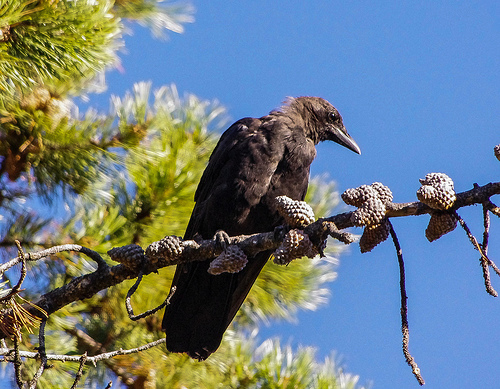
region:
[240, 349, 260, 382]
the tree has green leaves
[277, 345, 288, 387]
the tree has green leaves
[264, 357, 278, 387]
the tree has green leaves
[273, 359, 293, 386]
the tree has green leaves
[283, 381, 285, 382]
the tree has green leaves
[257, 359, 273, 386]
the tree has green leaves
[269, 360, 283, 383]
the tree has green leaves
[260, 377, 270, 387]
the tree has green leaves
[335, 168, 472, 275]
Pine cones on a branch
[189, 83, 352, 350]
Grey bird sitting on a branch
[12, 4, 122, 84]
Green pine needles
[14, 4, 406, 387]
Large bird sitting in a pine tree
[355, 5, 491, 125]
Clear azure blue sky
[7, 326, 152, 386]
Dead branch on tree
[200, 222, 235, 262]
Bird's feet grasping tree branch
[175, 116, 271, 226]
Bird's feathered wing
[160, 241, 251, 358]
Tail feathers of bird perched on tree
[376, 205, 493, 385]
Twigs on pine tree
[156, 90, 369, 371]
a black bird on a branch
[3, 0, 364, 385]
a pine tree behind a branch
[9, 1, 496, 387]
a beautiful blue sky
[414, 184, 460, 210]
a pine cone on a branch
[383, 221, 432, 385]
a long twig sticking off a branch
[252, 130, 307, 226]
the back breast on a bird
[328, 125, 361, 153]
a black bird beak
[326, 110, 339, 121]
a black beady eye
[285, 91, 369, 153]
the head of a black bird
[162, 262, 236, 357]
tail feathers on a black bird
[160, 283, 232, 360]
Bottom of bird tail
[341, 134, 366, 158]
Tip of bird beak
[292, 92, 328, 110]
Top of bird head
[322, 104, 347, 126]
Small bird black eye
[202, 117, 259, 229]
Black feather's on birds wing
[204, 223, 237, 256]
Black feet on bird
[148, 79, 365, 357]
Black bird on branch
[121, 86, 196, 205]
Green leaves on trees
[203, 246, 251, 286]
Acorn on tree branches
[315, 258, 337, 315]
White leaves on green trees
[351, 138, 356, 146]
beak of a bird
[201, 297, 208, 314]
part of a feather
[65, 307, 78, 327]
tip of a branch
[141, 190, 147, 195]
leaf of a plant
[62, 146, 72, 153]
edge of a plant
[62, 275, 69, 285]
part of a branch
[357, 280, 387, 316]
feather of a bird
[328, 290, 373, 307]
part of the sky